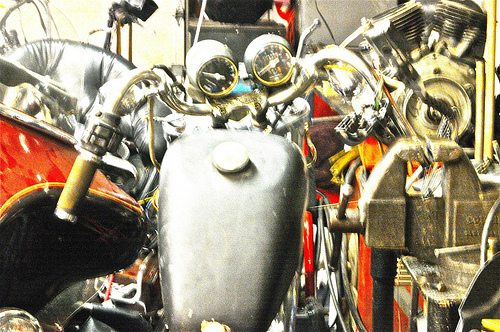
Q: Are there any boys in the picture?
A: No, there are no boys.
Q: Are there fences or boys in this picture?
A: No, there are no boys or fences.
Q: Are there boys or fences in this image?
A: No, there are no boys or fences.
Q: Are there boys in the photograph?
A: No, there are no boys.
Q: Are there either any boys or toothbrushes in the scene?
A: No, there are no boys or toothbrushes.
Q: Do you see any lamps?
A: No, there are no lamps.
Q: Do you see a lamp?
A: No, there are no lamps.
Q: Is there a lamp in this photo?
A: No, there are no lamps.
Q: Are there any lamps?
A: No, there are no lamps.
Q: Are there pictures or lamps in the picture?
A: No, there are no lamps or pictures.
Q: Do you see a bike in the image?
A: Yes, there is a bike.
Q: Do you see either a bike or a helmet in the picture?
A: Yes, there is a bike.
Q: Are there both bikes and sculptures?
A: No, there is a bike but no sculptures.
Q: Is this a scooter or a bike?
A: This is a bike.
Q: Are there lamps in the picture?
A: No, there are no lamps.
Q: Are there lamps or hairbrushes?
A: No, there are no lamps or hairbrushes.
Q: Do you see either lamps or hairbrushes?
A: No, there are no lamps or hairbrushes.